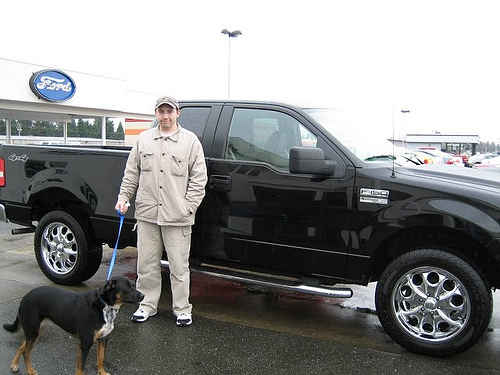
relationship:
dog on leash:
[21, 270, 143, 369] [89, 207, 149, 262]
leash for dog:
[104, 212, 126, 283] [0, 274, 144, 375]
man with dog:
[115, 98, 209, 329] [0, 274, 144, 375]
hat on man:
[154, 97, 182, 113] [115, 98, 209, 329]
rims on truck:
[373, 239, 493, 359] [0, 98, 492, 356]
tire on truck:
[29, 213, 99, 282] [0, 98, 492, 356]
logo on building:
[29, 68, 75, 107] [0, 52, 478, 210]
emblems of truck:
[357, 186, 391, 205] [0, 98, 492, 356]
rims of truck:
[373, 239, 493, 359] [0, 98, 492, 356]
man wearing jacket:
[115, 98, 209, 329] [117, 124, 210, 224]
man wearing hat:
[115, 98, 209, 329] [152, 94, 180, 115]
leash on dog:
[104, 212, 126, 283] [0, 274, 144, 375]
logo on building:
[29, 68, 75, 103] [1, 54, 401, 205]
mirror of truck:
[286, 146, 327, 176] [0, 98, 492, 356]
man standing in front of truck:
[115, 97, 209, 328] [0, 98, 492, 356]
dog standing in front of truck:
[0, 274, 144, 375] [0, 98, 492, 356]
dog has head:
[0, 274, 144, 375] [98, 276, 145, 311]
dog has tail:
[0, 274, 144, 375] [3, 295, 29, 335]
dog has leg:
[0, 274, 144, 375] [8, 334, 29, 373]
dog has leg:
[0, 274, 144, 375] [26, 331, 34, 368]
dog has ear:
[0, 274, 144, 375] [103, 283, 115, 302]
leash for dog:
[104, 212, 126, 278] [0, 274, 144, 375]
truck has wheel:
[0, 98, 492, 356] [379, 243, 487, 360]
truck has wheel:
[0, 98, 492, 356] [33, 214, 98, 281]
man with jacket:
[115, 98, 209, 329] [118, 125, 208, 231]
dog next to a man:
[0, 274, 144, 375] [115, 97, 209, 328]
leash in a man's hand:
[104, 212, 126, 283] [114, 193, 131, 215]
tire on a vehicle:
[29, 213, 99, 286] [6, 73, 482, 355]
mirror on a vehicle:
[285, 144, 345, 184] [6, 73, 482, 355]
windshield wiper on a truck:
[362, 150, 403, 161] [0, 98, 500, 356]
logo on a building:
[29, 68, 75, 103] [0, 49, 162, 146]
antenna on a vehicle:
[386, 98, 400, 185] [6, 73, 482, 355]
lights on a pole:
[217, 21, 246, 43] [220, 41, 236, 94]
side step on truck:
[138, 243, 355, 302] [0, 98, 500, 356]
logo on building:
[29, 68, 75, 103] [3, 54, 223, 142]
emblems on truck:
[355, 180, 393, 211] [0, 98, 492, 356]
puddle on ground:
[327, 288, 376, 314] [111, 290, 372, 366]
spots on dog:
[104, 304, 120, 324] [0, 274, 144, 375]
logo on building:
[29, 68, 75, 103] [1, 55, 154, 151]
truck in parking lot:
[0, 98, 500, 356] [10, 224, 480, 368]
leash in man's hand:
[104, 212, 126, 283] [106, 190, 131, 222]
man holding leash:
[115, 98, 209, 329] [105, 210, 125, 281]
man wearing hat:
[115, 98, 209, 329] [154, 95, 178, 108]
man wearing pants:
[115, 98, 209, 329] [134, 227, 192, 314]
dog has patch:
[0, 274, 144, 375] [97, 302, 121, 342]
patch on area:
[97, 302, 121, 342] [94, 303, 122, 338]